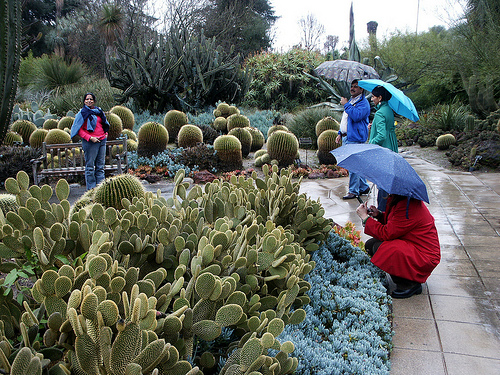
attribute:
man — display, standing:
[333, 77, 378, 155]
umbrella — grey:
[314, 56, 381, 86]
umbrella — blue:
[358, 73, 423, 124]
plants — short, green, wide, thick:
[1, 162, 320, 374]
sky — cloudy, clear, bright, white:
[141, 0, 488, 56]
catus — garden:
[47, 211, 252, 320]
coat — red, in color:
[371, 198, 452, 299]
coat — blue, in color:
[342, 102, 366, 154]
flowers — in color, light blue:
[288, 239, 402, 372]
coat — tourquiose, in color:
[370, 102, 399, 144]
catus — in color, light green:
[76, 208, 268, 320]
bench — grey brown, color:
[27, 141, 155, 185]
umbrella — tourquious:
[359, 70, 412, 141]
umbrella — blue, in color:
[339, 131, 431, 224]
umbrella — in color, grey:
[306, 40, 384, 106]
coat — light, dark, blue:
[69, 106, 110, 140]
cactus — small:
[3, 159, 325, 371]